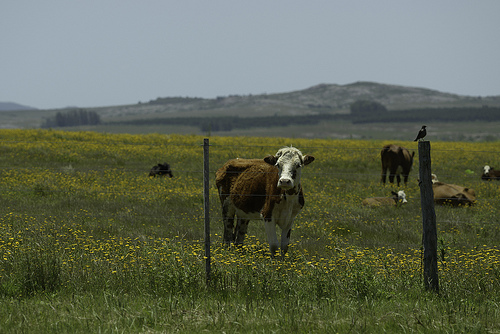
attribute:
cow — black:
[147, 161, 174, 177]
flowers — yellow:
[271, 252, 277, 253]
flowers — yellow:
[173, 251, 179, 258]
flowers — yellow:
[173, 234, 183, 237]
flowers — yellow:
[111, 270, 113, 274]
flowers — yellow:
[386, 253, 393, 258]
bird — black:
[413, 122, 428, 142]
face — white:
[481, 163, 491, 173]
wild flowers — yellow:
[12, 251, 396, 286]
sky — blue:
[1, 2, 498, 109]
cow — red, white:
[213, 145, 315, 257]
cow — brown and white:
[198, 142, 307, 278]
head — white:
[259, 140, 316, 190]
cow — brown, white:
[355, 179, 410, 211]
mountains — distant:
[101, 73, 471, 163]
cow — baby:
[360, 187, 407, 209]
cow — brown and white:
[219, 138, 303, 255]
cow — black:
[142, 160, 175, 180]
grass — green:
[26, 276, 496, 321]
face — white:
[277, 147, 297, 192]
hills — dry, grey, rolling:
[0, 77, 499, 139]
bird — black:
[411, 120, 430, 147]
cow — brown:
[379, 143, 415, 184]